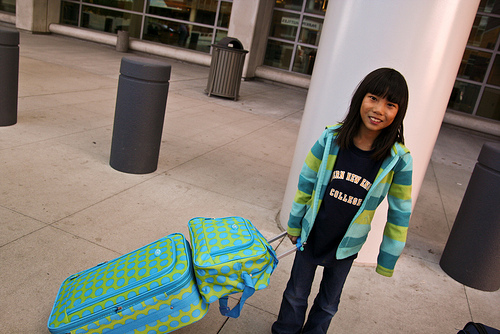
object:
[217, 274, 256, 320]
strap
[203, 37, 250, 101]
trash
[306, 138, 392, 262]
shirt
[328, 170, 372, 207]
letters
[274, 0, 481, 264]
pillar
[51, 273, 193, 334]
zipper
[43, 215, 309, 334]
luggage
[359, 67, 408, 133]
head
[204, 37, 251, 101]
dust bin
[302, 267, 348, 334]
leg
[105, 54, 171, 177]
pillar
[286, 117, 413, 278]
sweatshirt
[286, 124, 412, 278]
sweater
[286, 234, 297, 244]
hand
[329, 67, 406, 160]
hair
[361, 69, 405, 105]
bangs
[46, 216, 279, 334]
dots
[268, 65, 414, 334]
girl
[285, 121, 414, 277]
jacket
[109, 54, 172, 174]
cylinders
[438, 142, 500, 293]
cylinders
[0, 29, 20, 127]
cylinders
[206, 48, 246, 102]
lines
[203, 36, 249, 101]
can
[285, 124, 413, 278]
clothing (implied)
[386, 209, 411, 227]
stripe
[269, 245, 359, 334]
jeans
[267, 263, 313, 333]
leg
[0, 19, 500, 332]
sidewalk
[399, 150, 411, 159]
hooded